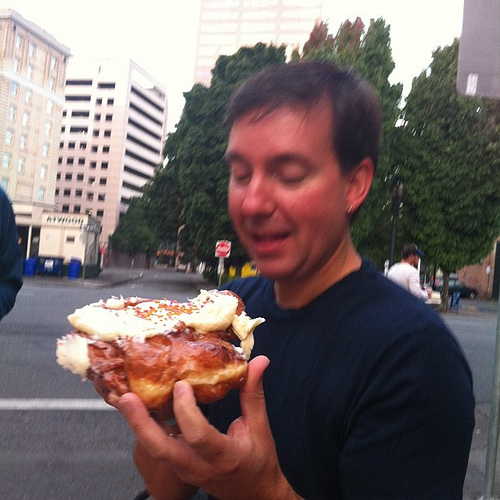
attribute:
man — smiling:
[109, 60, 477, 500]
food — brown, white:
[56, 288, 267, 424]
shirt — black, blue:
[134, 259, 476, 499]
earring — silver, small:
[348, 204, 356, 214]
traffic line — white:
[1, 395, 122, 411]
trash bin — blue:
[67, 259, 81, 279]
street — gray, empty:
[2, 266, 500, 499]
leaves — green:
[111, 17, 500, 270]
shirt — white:
[385, 261, 430, 304]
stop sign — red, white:
[216, 240, 232, 260]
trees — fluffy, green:
[109, 17, 500, 313]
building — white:
[39, 209, 103, 280]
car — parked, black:
[427, 277, 478, 300]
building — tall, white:
[195, 0, 325, 89]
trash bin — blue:
[24, 258, 36, 277]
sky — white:
[1, 1, 467, 172]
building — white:
[53, 56, 169, 266]